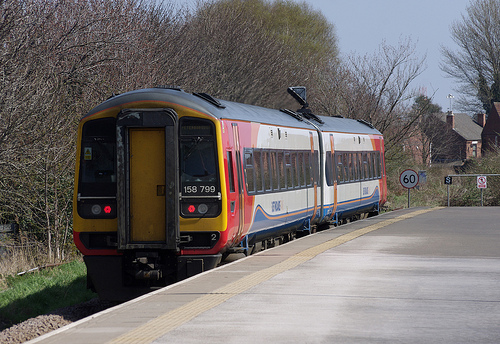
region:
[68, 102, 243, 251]
the back of the train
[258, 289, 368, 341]
the sidewalk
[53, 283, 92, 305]
a dark shadow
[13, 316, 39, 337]
the rocks are white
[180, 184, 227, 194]
numbers on the train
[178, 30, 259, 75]
tree branches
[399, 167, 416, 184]
a sign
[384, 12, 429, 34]
a clear sky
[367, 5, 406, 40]
the sky is clear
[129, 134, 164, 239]
a door on the train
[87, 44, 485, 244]
a train on the track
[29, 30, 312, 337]
a train on the train track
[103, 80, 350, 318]
a short train on the track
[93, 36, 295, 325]
a short train on the train tracks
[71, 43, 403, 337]
a passengr train on the train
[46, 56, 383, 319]
a passenger train on the train tracks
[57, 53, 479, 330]
a short passenger train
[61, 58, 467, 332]
a track with a train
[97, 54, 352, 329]
a track with apssenger train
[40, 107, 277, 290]
a track with a short train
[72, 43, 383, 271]
Train parked beside the waiting area.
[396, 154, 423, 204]
Sign beside the train.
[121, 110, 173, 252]
Front door of the train.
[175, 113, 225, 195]
Window of the front of the train.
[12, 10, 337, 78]
Trees lining the tracks.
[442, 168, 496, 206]
Metal fencing enclosing the pedway.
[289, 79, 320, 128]
Antenna on top of train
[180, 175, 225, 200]
Train number in the window.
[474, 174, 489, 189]
Sign hanging on metal fence.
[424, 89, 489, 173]
House in the background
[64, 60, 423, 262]
a white train with red blue and orange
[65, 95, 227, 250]
yellow on front of train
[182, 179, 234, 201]
white numbers on front of train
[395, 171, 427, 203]
a white sign with black numbers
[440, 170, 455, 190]
a black sign with white number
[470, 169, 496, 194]
a red and white sign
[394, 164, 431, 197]
a round white sign with red trim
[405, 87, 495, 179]
a house with a chimney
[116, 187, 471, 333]
yellow line on the concrete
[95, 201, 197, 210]
two red lights on front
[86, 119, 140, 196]
window of a train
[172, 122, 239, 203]
window of a train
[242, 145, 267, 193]
window of a train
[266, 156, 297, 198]
window of a train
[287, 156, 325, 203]
window of a train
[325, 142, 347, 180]
window of a train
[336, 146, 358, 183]
window of a train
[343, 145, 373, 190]
window of a train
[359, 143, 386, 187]
window of a train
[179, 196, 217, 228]
light of a train